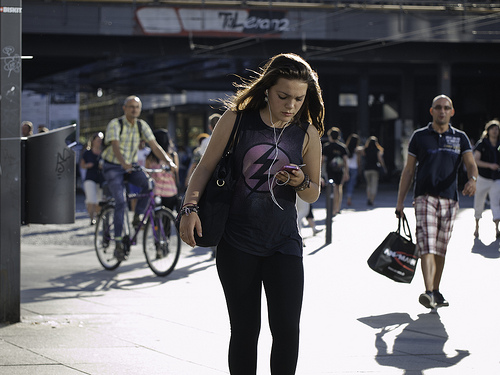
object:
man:
[395, 94, 478, 311]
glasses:
[432, 106, 451, 110]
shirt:
[408, 122, 472, 202]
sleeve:
[459, 133, 473, 155]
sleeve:
[408, 131, 419, 157]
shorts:
[413, 195, 459, 258]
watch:
[468, 176, 477, 182]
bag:
[367, 210, 418, 284]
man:
[101, 95, 178, 261]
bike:
[94, 150, 181, 276]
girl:
[175, 52, 325, 375]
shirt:
[223, 110, 310, 258]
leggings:
[216, 238, 304, 375]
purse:
[175, 111, 236, 247]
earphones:
[265, 89, 306, 211]